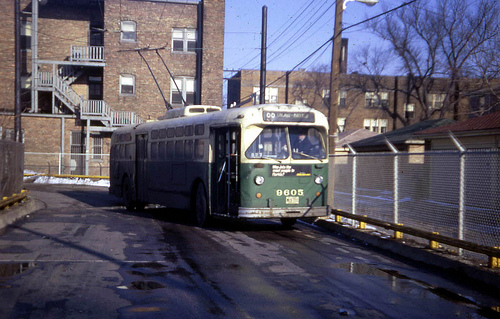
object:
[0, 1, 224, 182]
apartment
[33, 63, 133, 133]
staircase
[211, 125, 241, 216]
door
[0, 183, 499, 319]
ground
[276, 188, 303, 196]
number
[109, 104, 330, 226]
bus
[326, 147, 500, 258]
fence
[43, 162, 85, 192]
snow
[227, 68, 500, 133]
apartment building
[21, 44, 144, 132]
metal stairway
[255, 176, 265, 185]
headlight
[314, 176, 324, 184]
headlight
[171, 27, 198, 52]
window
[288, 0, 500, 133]
trees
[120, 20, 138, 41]
window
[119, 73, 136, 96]
window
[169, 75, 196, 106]
window